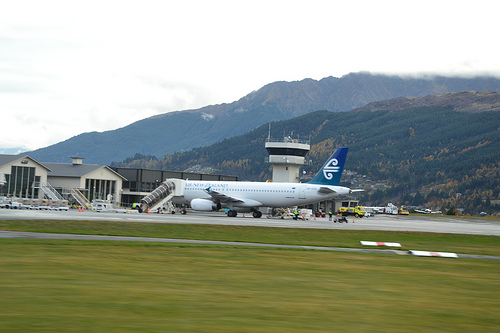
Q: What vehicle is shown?
A: A plane.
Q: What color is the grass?
A: Green.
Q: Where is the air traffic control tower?
A: Behind the plane.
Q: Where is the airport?
A: In front of the hills.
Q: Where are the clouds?
A: In the sky.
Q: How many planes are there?
A: One.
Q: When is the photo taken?
A: Daytime.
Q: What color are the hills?
A: Green and brown.